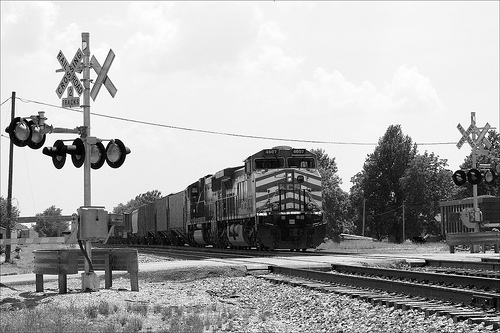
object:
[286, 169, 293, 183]
lights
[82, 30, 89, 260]
pole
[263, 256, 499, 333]
railroad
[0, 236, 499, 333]
ground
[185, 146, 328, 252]
engine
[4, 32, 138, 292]
section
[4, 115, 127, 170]
train lights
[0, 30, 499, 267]
railroad crossing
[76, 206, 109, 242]
box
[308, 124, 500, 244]
tree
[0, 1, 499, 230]
sky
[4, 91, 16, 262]
pole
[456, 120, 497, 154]
crossingsign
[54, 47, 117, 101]
crossingsign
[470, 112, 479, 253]
pole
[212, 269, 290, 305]
rocks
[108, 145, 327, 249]
train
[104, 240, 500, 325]
railroad tracks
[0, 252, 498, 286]
road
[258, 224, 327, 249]
guard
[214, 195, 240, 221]
railings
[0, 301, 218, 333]
grass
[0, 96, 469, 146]
wire